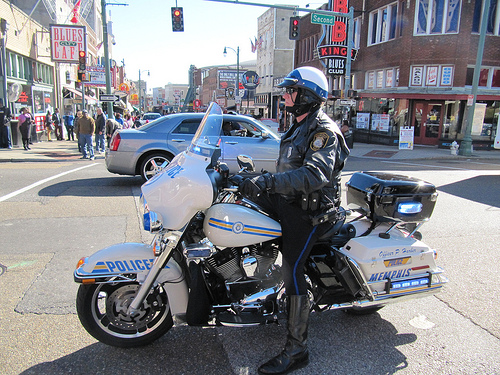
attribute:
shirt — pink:
[15, 112, 30, 128]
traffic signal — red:
[289, 17, 299, 26]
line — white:
[2, 160, 101, 201]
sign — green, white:
[307, 13, 337, 25]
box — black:
[376, 170, 446, 211]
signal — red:
[170, 7, 182, 20]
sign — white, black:
[100, 93, 120, 105]